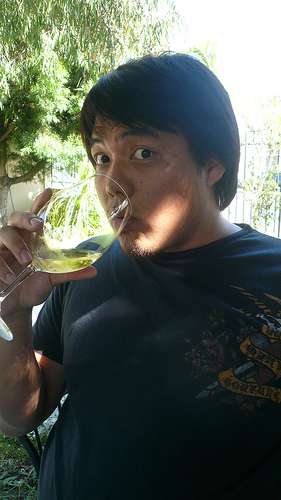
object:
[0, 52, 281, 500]
man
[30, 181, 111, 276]
wine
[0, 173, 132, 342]
glass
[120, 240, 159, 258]
beard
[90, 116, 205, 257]
face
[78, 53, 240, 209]
hair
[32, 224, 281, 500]
shirt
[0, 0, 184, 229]
tree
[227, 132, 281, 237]
fence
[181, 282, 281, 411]
design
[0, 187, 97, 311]
hand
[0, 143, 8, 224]
trunk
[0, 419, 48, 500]
grass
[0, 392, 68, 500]
ground